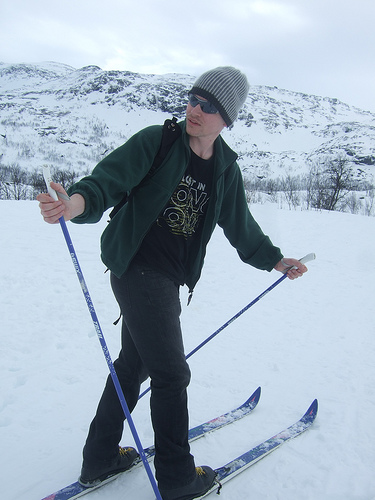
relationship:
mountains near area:
[0, 59, 373, 218] [0, 198, 373, 498]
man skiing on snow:
[67, 23, 332, 262] [315, 202, 352, 267]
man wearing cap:
[36, 66, 307, 499] [189, 53, 253, 128]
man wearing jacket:
[36, 66, 307, 499] [66, 119, 284, 304]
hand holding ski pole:
[277, 250, 304, 280] [138, 252, 315, 400]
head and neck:
[187, 67, 250, 137] [188, 135, 216, 159]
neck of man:
[188, 135, 216, 159] [36, 66, 307, 499]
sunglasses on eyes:
[186, 91, 218, 116] [185, 88, 222, 115]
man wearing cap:
[36, 66, 307, 499] [187, 61, 252, 130]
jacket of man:
[66, 119, 284, 304] [36, 66, 307, 499]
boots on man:
[54, 425, 217, 490] [36, 66, 307, 499]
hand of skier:
[30, 174, 76, 232] [44, 64, 330, 495]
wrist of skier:
[63, 183, 82, 227] [44, 64, 330, 495]